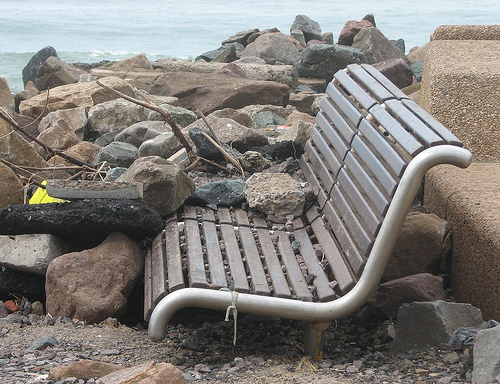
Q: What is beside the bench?
A: Rocks.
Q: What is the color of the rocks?
A: Black and brown.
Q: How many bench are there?
A: One.